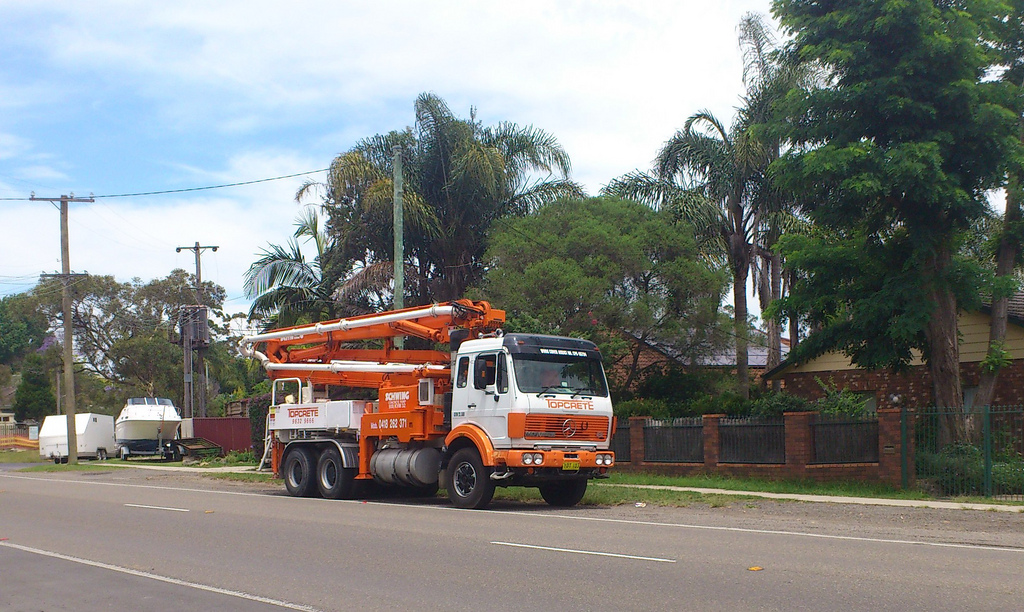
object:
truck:
[236, 298, 616, 509]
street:
[0, 461, 1022, 612]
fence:
[810, 410, 879, 464]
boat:
[115, 397, 183, 461]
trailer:
[39, 413, 116, 464]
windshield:
[510, 353, 608, 397]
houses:
[759, 278, 1022, 480]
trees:
[747, 0, 1020, 457]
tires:
[444, 447, 494, 508]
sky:
[2, 0, 1023, 342]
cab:
[444, 333, 614, 481]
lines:
[0, 542, 325, 611]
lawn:
[0, 448, 287, 485]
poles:
[60, 195, 76, 464]